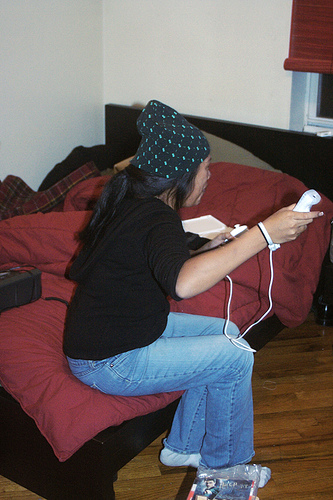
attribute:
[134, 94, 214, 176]
hat — knitted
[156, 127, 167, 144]
dots — blue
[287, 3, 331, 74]
blinds — brownish red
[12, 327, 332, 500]
floors — hardwood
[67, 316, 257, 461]
jeans — blue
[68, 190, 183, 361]
shirt — black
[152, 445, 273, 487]
socks — grey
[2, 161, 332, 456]
blanket — burgundy, red, plain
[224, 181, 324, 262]
wiimote — white